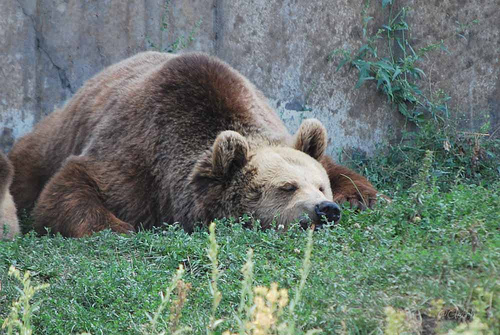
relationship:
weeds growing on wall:
[335, 0, 447, 145] [218, 2, 496, 139]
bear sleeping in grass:
[0, 50, 394, 237] [2, 235, 493, 335]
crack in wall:
[18, 2, 74, 93] [218, 2, 496, 139]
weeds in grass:
[207, 218, 225, 334] [2, 235, 493, 335]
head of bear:
[211, 117, 337, 231] [0, 50, 394, 237]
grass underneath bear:
[2, 235, 493, 335] [0, 50, 394, 237]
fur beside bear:
[1, 152, 14, 201] [0, 50, 394, 237]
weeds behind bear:
[340, 127, 429, 201] [0, 50, 394, 237]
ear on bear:
[296, 117, 328, 162] [0, 50, 394, 237]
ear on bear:
[212, 129, 248, 183] [0, 50, 394, 237]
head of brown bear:
[211, 117, 337, 231] [0, 50, 394, 237]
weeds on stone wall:
[335, 0, 447, 145] [218, 2, 496, 139]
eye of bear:
[279, 183, 298, 193] [0, 50, 394, 237]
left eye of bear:
[319, 186, 325, 192] [0, 50, 394, 237]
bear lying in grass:
[0, 50, 394, 237] [2, 235, 493, 335]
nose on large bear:
[315, 201, 341, 225] [0, 50, 394, 237]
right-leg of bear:
[31, 156, 136, 239] [0, 50, 394, 237]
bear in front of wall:
[0, 50, 394, 237] [218, 2, 496, 139]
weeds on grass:
[1, 266, 51, 334] [2, 235, 493, 335]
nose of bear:
[315, 201, 341, 225] [0, 50, 394, 237]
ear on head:
[296, 117, 328, 162] [211, 117, 337, 231]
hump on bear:
[132, 52, 250, 84] [0, 50, 394, 237]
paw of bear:
[334, 190, 392, 211] [0, 50, 394, 237]